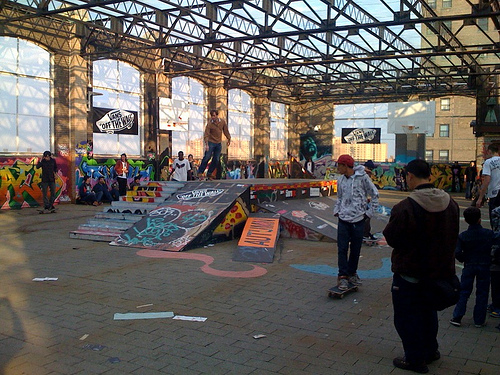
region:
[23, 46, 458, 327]
an indoor skatepark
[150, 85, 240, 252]
a bor skateboarding on a ramp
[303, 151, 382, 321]
a boy with a red hat skateboarding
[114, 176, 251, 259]
grafitti on a ramp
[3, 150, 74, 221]
a boy in front of yellow and red grafitti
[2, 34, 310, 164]
5 windows in a row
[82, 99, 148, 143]
a black and white sign in a window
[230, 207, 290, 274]
a black and orange ramp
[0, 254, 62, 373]
the shadow's of someone's arm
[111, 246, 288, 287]
a red shape on the floor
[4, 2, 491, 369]
an open air warehouse converted into a skate park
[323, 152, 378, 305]
a boy on a skateboard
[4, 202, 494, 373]
the floors are tiled in the skate park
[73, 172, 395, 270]
wooden jumps for the skateboarders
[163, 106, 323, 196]
three skateboarders are using the ramps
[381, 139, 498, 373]
spectators line the side of the park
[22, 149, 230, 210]
spectators are under the windows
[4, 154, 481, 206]
graffiti is colorful along the walls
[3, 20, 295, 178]
the windows are arched on the side of the park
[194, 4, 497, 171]
buildings are behind the skate park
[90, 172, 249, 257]
a skateboard ramp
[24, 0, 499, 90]
black metal rafters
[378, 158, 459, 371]
man in black coat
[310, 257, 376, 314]
a grey skateboard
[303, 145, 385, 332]
man on grey skateboard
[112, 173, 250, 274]
skateboard ramp with graffiti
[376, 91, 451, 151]
a basket ball net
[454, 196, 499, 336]
small boy in blue coat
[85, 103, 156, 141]
black sign with white logo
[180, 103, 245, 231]
man skate boarding on ramp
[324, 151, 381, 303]
boy standing on skateboard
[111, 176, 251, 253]
black skateboard ramp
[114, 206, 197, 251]
blue and white graffiti on skateboard ramp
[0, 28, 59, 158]
six pane glass window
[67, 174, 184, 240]
cement skateboard steps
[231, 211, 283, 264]
orange sign on black skateboard ramp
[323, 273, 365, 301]
black skateboard on ground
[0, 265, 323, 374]
brown brick ground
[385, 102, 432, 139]
orange basketball hoop attached to white backboard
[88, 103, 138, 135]
black and white banner on window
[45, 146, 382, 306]
skateboarding ramp with graffiti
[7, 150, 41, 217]
graffiti covering building walls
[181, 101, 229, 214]
man skateboarding on ramp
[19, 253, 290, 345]
litter on the ground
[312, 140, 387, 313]
person on skateboard with red hat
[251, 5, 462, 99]
black metal rafters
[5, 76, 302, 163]
set of five tall windows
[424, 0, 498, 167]
tall brick building in the background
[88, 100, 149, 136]
advertisement hung on window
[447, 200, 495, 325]
young child watching skateboarders